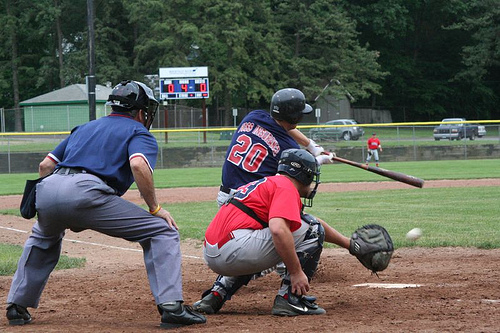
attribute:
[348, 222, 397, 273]
glove — catcher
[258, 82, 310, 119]
helmet — black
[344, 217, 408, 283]
catcher's mitt — black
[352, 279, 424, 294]
base — white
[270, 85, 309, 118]
helmet — black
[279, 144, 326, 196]
helmet — black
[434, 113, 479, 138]
vehicle — pickup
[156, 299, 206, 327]
sneaker — black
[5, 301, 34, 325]
sneaker — black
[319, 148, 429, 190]
bat — long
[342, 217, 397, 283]
glove — black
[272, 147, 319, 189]
helmet — black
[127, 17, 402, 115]
forest — dense, green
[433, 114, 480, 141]
truck — black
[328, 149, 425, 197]
bat — brown, wooden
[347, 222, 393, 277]
mitt — black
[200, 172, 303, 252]
shirt — red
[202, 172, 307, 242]
shirt — red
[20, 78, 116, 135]
building — green